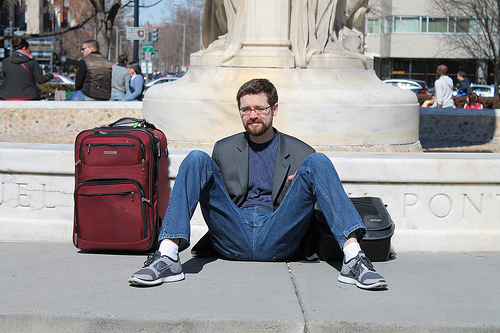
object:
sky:
[115, 0, 202, 28]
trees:
[421, 2, 499, 97]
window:
[391, 15, 421, 34]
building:
[361, 2, 498, 95]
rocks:
[0, 107, 142, 145]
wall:
[0, 98, 146, 150]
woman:
[122, 59, 147, 103]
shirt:
[122, 73, 147, 103]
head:
[233, 76, 280, 137]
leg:
[157, 150, 240, 250]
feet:
[125, 252, 186, 289]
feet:
[334, 251, 389, 290]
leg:
[264, 151, 369, 263]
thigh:
[201, 175, 250, 262]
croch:
[240, 202, 265, 266]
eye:
[238, 104, 249, 114]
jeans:
[153, 148, 368, 262]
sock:
[154, 238, 182, 261]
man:
[124, 77, 387, 290]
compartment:
[72, 178, 152, 246]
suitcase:
[71, 115, 173, 252]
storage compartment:
[74, 178, 152, 245]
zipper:
[68, 177, 150, 241]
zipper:
[82, 141, 137, 149]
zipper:
[75, 188, 140, 197]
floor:
[0, 240, 499, 328]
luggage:
[309, 194, 393, 264]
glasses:
[235, 104, 272, 117]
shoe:
[335, 250, 387, 290]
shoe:
[126, 249, 185, 287]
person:
[0, 36, 54, 101]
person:
[67, 39, 112, 102]